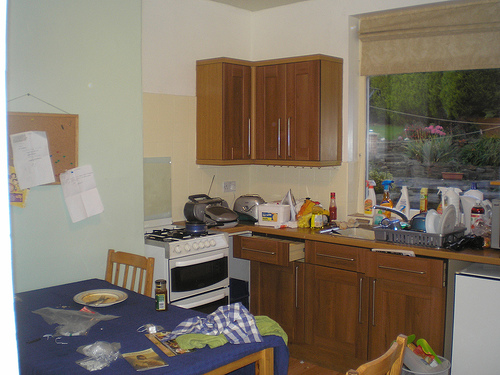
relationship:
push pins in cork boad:
[53, 145, 69, 165] [10, 109, 82, 191]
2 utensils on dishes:
[86, 295, 115, 311] [69, 278, 132, 309]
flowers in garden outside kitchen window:
[407, 122, 448, 144] [364, 38, 496, 188]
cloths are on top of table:
[148, 305, 294, 357] [41, 278, 288, 370]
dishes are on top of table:
[41, 262, 146, 371] [17, 270, 283, 373]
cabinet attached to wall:
[189, 51, 349, 168] [142, 47, 195, 160]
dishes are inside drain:
[369, 189, 483, 246] [368, 185, 469, 254]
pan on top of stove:
[152, 216, 234, 242] [141, 214, 230, 316]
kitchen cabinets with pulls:
[230, 227, 445, 367] [358, 276, 376, 326]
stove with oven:
[141, 157, 230, 316] [167, 247, 234, 304]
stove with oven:
[141, 157, 230, 316] [172, 287, 232, 318]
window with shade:
[354, 3, 495, 244] [358, 4, 498, 74]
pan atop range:
[171, 219, 220, 242] [144, 216, 231, 316]